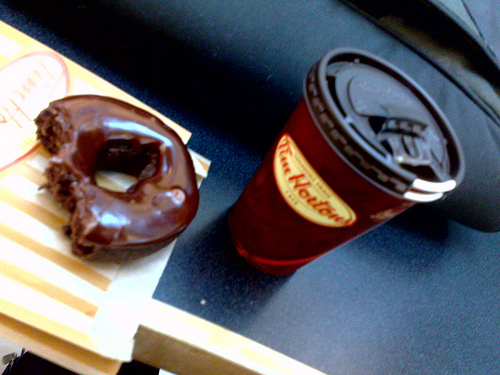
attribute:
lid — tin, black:
[299, 38, 479, 195]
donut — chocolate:
[23, 79, 203, 259]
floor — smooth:
[395, 275, 495, 346]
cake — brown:
[31, 93, 201, 264]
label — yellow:
[270, 132, 355, 232]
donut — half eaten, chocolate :
[51, 115, 181, 219]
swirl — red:
[236, 246, 313, 268]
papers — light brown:
[27, 245, 146, 355]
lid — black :
[302, 35, 468, 208]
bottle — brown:
[235, 44, 435, 300]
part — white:
[404, 176, 455, 204]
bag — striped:
[21, 199, 199, 353]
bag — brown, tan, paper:
[0, 211, 139, 374]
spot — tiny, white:
[197, 296, 207, 306]